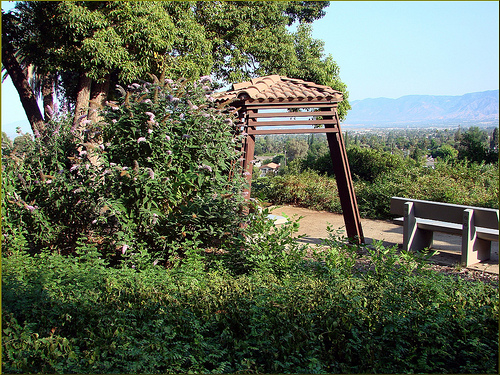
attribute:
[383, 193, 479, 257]
bench — cement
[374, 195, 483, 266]
bench — cement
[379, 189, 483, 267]
bench — cement, during the day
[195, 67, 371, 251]
canopy — tall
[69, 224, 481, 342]
bushes — green 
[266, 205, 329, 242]
floor — brown 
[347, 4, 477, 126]
sky — blue 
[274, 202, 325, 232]
land — above 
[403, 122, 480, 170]
trees — green , distance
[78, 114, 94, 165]
flowers — bright 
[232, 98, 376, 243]
structure — top 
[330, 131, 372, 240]
pillar — brown 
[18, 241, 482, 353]
bush — green 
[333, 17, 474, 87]
sky — blue  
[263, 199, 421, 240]
land — above 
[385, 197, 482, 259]
bench — back 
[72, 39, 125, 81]
branches — brown 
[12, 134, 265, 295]
trees — background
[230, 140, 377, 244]
legs — Support 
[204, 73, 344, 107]
roof — tiled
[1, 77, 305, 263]
bush — flowered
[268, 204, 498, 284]
path — concrete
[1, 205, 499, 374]
plants — green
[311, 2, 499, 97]
sky — pale, blue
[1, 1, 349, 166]
trees — leafy, green